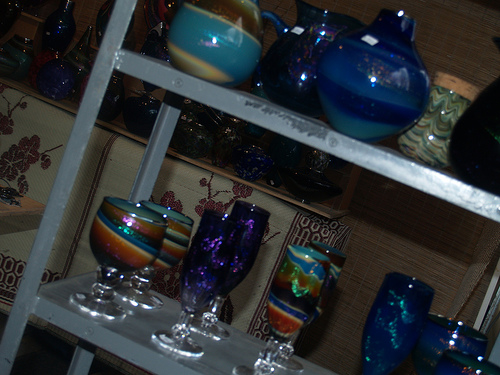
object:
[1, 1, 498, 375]
unit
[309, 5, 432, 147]
vase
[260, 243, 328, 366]
goblets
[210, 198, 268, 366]
glasses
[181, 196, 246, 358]
glasses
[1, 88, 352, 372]
tapestry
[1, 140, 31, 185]
flowers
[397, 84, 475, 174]
glass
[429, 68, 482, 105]
cork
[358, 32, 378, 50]
sticker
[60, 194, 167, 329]
glasses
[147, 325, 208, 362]
bottom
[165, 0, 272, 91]
glass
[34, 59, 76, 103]
glass